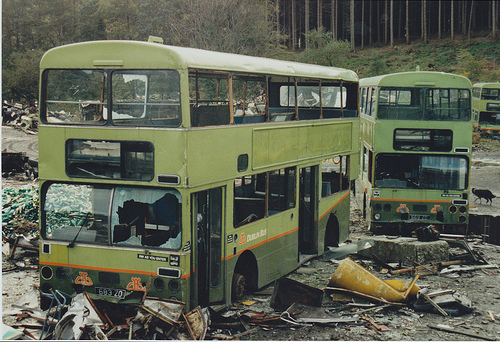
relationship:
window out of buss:
[97, 173, 184, 271] [29, 39, 363, 288]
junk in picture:
[7, 30, 497, 340] [10, 22, 495, 332]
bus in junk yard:
[30, 34, 362, 315] [4, 6, 484, 334]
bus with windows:
[29, 37, 358, 300] [108, 173, 188, 249]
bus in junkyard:
[29, 37, 358, 300] [20, 30, 486, 327]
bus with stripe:
[29, 37, 358, 300] [37, 254, 197, 284]